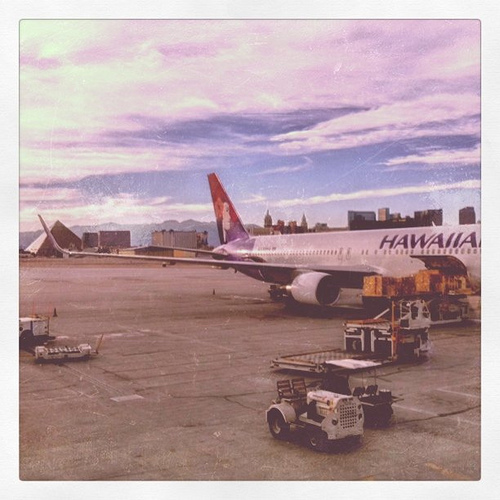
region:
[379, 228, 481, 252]
hawaiin airline airplane in parking lot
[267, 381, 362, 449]
luggage mover in airport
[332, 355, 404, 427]
golf cart sitting in parking lot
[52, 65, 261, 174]
clouds in the skies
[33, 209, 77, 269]
pyramid building in skyline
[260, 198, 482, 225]
city skyline by airport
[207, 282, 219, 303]
cone behind the airplane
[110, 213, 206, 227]
mountain range in the distance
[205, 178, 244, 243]
Hawaiin airline logo on tail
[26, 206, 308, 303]
right wing on the airplane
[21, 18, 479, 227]
sky full of pink, purple, and white clouds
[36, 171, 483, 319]
red, white, and blue plane parked on pavement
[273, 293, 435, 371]
a white loader beside the plane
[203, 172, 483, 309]
a plane with the letters HAWAIIA on the side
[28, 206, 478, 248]
building in the background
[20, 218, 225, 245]
tree covered hills behind the buildings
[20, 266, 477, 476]
concrete pavement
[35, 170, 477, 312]
the plane has a row of windows down the side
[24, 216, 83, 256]
building shaped like a pyramid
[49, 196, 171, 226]
sun shining from behind the clouds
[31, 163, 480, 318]
a plane in the airport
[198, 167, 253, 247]
vertical stabilizer is red and blue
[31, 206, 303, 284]
left wing of plane is long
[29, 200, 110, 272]
tip of plane is bend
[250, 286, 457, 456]
carts in front of aircraft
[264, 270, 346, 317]
an engine below a wing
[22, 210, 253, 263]
mountains on the background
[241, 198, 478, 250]
buildings on back of plane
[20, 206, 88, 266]
a pyramidal building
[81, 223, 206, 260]
buildings on the background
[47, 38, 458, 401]
This picture looks vintage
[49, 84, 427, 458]
This looks like evening time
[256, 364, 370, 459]
This is a vehicle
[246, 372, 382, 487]
This vehicle is used to move luggage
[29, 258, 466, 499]
This is on a runway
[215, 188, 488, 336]
this is an airplane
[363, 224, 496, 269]
This is a Hawaiian Airlines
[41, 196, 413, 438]
This is at an airport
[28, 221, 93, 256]
This is a pyramid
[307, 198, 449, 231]
These buildings are towers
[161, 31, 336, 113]
A beautiful purple sky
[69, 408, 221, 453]
A grey concrete floor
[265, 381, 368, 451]
A strong white truck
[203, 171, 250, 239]
A large aeroplane tail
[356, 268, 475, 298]
An enormous airport machine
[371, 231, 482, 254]
A HAWAIIA airlines aeroplane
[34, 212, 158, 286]
An enormous aeroplane wing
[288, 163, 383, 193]
Patch of clear sky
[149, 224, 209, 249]
Big ugly white buildings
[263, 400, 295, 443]
A big wheel truck